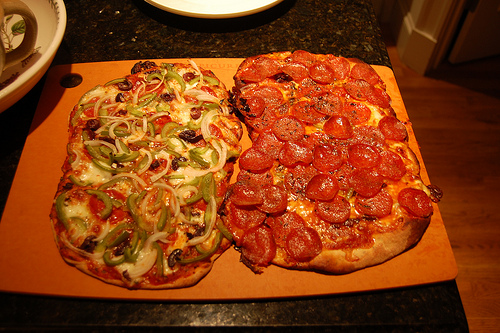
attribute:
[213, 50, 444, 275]
pizza — pepperoni, unusually shaped, large, homemade, oval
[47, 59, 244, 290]
pizza — homemade, oval, vegetarian, large, supreme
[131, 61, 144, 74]
black olive — slived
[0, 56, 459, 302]
tray — brown, wooden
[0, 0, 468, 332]
counter top — dark, granite, black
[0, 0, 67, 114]
bowl — white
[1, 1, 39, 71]
cup — white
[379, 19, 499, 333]
floor — wooden, hardwood, for walking on, clean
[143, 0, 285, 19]
plate — round, white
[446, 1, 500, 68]
door — open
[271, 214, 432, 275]
crust — brown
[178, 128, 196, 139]
black olive — sliced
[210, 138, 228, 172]
onion slice — white